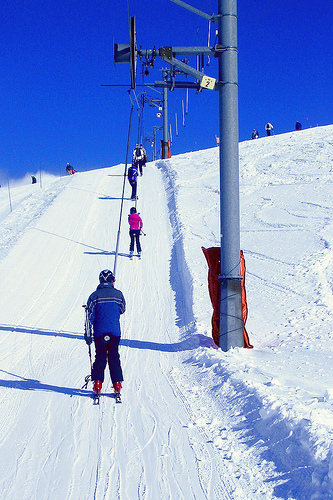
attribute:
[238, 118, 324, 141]
people — on top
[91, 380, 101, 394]
boot — red, mounted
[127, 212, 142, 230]
jacket — long sleeved, pink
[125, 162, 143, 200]
person — going up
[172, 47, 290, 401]
poles — large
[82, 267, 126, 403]
skier — responsible, wearing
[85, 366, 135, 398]
boots — red, ski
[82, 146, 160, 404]
people — going up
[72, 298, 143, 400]
skier — wearing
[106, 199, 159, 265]
skier — wearing, blue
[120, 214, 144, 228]
jacket — bright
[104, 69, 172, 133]
ski tow — rope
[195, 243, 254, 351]
pad — orange, safety